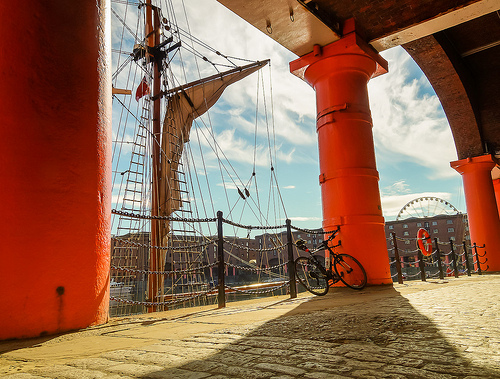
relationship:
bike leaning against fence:
[286, 235, 373, 298] [111, 205, 336, 292]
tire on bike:
[332, 253, 369, 290] [290, 223, 370, 295]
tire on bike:
[293, 253, 331, 296] [290, 223, 370, 295]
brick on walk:
[338, 331, 408, 354] [7, 270, 498, 372]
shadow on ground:
[135, 287, 499, 377] [1, 271, 499, 377]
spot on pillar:
[55, 284, 65, 298] [0, 0, 112, 341]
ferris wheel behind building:
[388, 196, 474, 278] [5, 0, 499, 379]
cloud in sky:
[112, 2, 479, 206] [101, 0, 498, 250]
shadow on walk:
[135, 287, 499, 377] [7, 270, 498, 372]